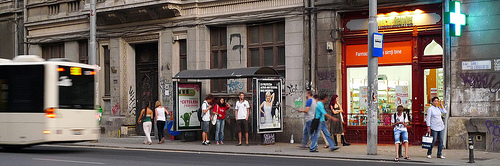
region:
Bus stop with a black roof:
[170, 65, 285, 143]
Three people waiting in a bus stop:
[197, 87, 253, 147]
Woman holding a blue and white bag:
[420, 96, 447, 160]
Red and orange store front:
[338, 8, 445, 142]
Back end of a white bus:
[0, 52, 102, 152]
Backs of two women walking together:
[136, 97, 169, 144]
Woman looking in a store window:
[329, 91, 349, 147]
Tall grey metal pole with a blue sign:
[366, 1, 383, 155]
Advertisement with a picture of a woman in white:
[256, 77, 283, 131]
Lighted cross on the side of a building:
[445, 1, 467, 38]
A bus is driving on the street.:
[0, 53, 103, 152]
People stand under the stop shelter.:
[172, 65, 284, 145]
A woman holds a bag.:
[419, 122, 434, 147]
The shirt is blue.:
[312, 100, 325, 121]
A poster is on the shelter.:
[256, 80, 281, 130]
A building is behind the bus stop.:
[107, 1, 300, 62]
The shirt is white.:
[235, 100, 249, 117]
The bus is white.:
[59, 113, 94, 139]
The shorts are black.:
[235, 119, 246, 131]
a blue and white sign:
[371, 32, 383, 54]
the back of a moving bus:
[1, 53, 98, 155]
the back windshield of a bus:
[56, 66, 95, 110]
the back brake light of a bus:
[46, 106, 56, 118]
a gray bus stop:
[169, 67, 284, 148]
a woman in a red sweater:
[213, 95, 230, 144]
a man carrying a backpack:
[387, 104, 412, 161]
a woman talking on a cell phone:
[425, 94, 448, 156]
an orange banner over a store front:
[345, 42, 410, 67]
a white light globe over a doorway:
[420, 37, 444, 62]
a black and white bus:
[8, 40, 111, 157]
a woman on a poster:
[253, 82, 285, 137]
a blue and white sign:
[366, 28, 391, 80]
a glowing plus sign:
[437, 4, 472, 44]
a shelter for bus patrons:
[150, 49, 315, 164]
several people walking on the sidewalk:
[116, 72, 490, 164]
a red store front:
[335, 18, 451, 150]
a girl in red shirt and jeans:
[210, 94, 235, 143]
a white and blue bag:
[418, 125, 443, 161]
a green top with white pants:
[136, 103, 165, 155]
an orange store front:
[339, 34, 416, 152]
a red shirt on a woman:
[213, 102, 228, 119]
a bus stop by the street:
[170, 65, 285, 147]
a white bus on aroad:
[0, 51, 105, 151]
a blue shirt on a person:
[313, 99, 330, 122]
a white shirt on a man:
[233, 98, 250, 116]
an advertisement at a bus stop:
[253, 77, 285, 136]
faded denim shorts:
[393, 127, 410, 147]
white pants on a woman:
[141, 120, 153, 142]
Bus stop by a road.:
[163, 54, 289, 153]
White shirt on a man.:
[234, 97, 249, 122]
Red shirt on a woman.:
[214, 101, 227, 118]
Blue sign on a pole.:
[368, 30, 385, 59]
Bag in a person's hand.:
[418, 133, 434, 150]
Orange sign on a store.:
[341, 38, 416, 67]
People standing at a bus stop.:
[196, 93, 257, 143]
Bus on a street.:
[1, 52, 104, 156]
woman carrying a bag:
[420, 94, 446, 160]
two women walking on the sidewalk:
[135, 98, 167, 145]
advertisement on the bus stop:
[257, 78, 280, 129]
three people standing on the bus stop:
[196, 90, 247, 145]